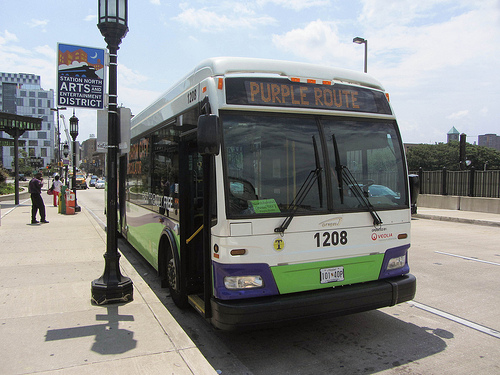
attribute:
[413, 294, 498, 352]
line — white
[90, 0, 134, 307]
lamp — black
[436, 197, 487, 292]
street — large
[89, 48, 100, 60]
moon — white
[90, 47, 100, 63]
moon — white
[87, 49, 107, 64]
moon — white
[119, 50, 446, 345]
bus — green, white, city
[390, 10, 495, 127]
clouds — light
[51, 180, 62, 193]
blouse — white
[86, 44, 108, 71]
moon — white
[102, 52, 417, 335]
bus — green, purple, white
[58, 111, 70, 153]
crane — construction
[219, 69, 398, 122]
sign — digital